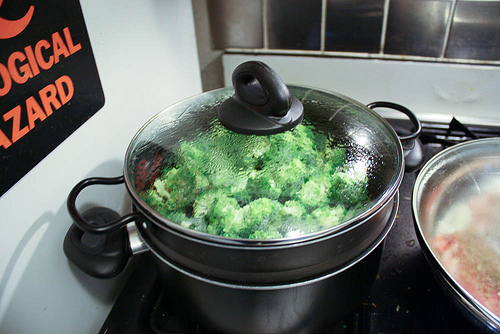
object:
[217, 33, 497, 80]
trim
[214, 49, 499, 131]
wall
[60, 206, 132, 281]
handle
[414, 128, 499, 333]
glass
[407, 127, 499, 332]
fry pan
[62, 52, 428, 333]
double boiler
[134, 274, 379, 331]
burner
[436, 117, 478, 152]
control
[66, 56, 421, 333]
range top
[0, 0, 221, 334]
wall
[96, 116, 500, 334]
stove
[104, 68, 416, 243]
pot lid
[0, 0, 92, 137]
letter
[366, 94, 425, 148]
handle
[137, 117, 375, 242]
broccoli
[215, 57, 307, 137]
handle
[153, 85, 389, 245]
glass